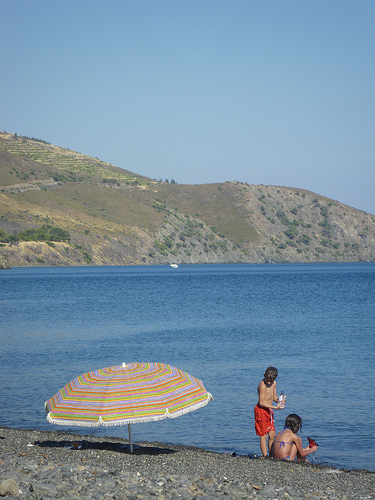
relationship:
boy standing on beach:
[252, 366, 285, 458] [4, 454, 259, 498]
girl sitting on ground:
[272, 413, 317, 462] [43, 158, 262, 234]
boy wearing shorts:
[252, 366, 285, 458] [253, 404, 276, 435]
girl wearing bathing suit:
[273, 413, 318, 462] [271, 437, 292, 460]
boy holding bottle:
[252, 366, 285, 458] [277, 393, 285, 405]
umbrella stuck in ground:
[44, 361, 214, 453] [0, 447, 373, 495]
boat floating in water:
[165, 259, 181, 271] [93, 270, 271, 302]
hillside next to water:
[0, 131, 373, 266] [1, 259, 374, 472]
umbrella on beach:
[44, 361, 212, 453] [0, 428, 373, 498]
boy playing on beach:
[252, 366, 285, 458] [2, 262, 372, 498]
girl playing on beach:
[272, 413, 317, 462] [2, 262, 372, 498]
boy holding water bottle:
[252, 366, 285, 458] [274, 390, 285, 409]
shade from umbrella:
[31, 435, 179, 462] [40, 355, 217, 453]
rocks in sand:
[46, 472, 143, 493] [6, 428, 330, 496]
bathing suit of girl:
[274, 428, 295, 460] [271, 411, 320, 462]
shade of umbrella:
[31, 435, 179, 456] [32, 343, 224, 437]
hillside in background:
[0, 131, 373, 266] [1, 99, 372, 279]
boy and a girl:
[252, 366, 285, 458] [272, 413, 317, 462]